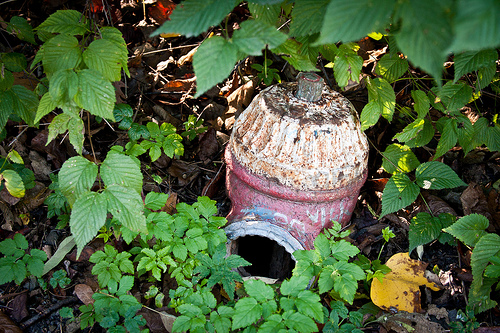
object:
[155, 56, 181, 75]
leaflets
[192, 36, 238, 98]
leafs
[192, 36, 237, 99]
leaf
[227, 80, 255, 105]
brown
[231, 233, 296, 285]
hole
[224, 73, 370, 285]
hydrant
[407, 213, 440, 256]
leaf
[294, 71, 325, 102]
bolt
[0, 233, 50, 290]
plant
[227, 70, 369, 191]
top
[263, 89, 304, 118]
dirt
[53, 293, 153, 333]
plants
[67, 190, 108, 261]
four leaves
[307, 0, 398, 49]
leaves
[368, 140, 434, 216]
thin branch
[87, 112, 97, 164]
twig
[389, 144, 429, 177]
sunlight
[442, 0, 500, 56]
leaves